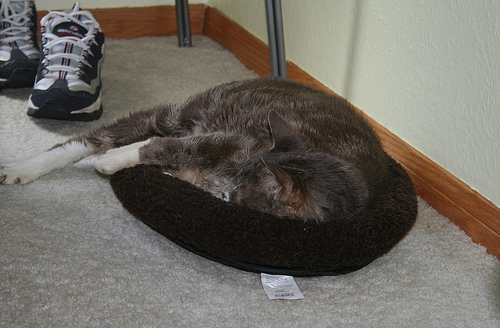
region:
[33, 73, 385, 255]
a cat laying in a pet bed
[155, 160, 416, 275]
a black pet bed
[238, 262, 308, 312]
a white tag on a pet bed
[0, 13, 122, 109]
a pair of tennis shoes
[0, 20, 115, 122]
a pair of tennis shoes on the floor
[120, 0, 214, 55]
wood base board around a room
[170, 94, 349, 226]
a cat sleeping in a pet bed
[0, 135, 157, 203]
a cat with white feet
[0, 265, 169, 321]
carpeting on a floor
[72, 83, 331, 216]
a grey cat with white feet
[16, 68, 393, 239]
a grey and white cat laying on a bed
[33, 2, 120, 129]
a blue and white sneaker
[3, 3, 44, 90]
a blue and white sneaker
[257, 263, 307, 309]
a white cat bed tag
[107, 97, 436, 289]
a brown cat bed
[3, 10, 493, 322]
white carpet on the floor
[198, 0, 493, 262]
a wooden base board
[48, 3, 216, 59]
a wooden base board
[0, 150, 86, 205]
a white cat paw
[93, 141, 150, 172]
a white cat paw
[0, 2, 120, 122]
pair of tennis shoes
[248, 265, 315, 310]
white tag on cat bed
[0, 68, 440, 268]
brown and white cat sleeping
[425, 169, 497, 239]
brown wooden floor trim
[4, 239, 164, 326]
white carpet on floor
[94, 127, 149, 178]
white paw on cat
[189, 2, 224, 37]
gap in wooden floor moulding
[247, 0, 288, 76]
silver metal table leg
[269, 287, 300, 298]
black text on white tag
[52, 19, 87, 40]
company name on tennis shoe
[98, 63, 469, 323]
a cat in a bed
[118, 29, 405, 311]
a cat laying on a bed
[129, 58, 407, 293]
a cat with white pays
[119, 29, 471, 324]
a cat laying inside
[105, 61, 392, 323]
an inside cat laying down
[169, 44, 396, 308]
a cat in a cat bed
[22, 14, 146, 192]
shoes on teh ground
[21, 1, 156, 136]
shoes on the carpet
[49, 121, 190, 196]
white cat paws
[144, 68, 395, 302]
a cat that is sleeping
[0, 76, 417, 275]
A cat napping in a cat bed.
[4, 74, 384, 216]
Brown and white cat.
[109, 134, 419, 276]
A black cat bed.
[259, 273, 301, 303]
White tag on the cat bed.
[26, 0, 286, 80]
Metal chair legs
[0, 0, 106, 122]
A pair of black and white sneakers.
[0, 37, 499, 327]
Tan carpet on the floor.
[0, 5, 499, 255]
Wooden wall base around the lower wall.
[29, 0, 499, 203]
White paint on the walls.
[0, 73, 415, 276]
A cozy cat in a black cat bed.